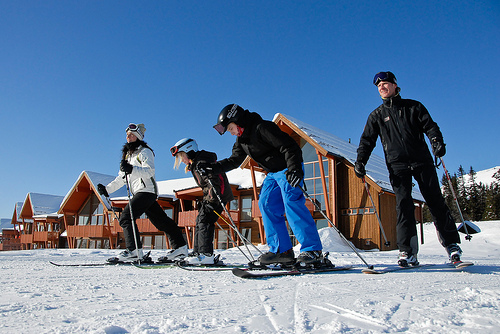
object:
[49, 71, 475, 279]
family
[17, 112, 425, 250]
ski lodge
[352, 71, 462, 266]
father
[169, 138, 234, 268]
children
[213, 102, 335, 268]
mother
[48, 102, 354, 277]
skiers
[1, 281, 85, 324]
slopes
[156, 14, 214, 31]
sky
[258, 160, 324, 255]
pants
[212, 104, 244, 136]
helmet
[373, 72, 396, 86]
goggles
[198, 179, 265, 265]
ski pole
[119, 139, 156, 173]
scarf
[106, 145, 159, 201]
jacket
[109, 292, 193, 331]
tracks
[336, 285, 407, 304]
snow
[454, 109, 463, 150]
clouds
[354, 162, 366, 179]
hand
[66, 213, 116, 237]
balcony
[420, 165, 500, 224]
trees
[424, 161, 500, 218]
background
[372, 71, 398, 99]
head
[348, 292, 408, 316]
ground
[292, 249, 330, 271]
boot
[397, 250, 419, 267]
foot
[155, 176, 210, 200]
roof